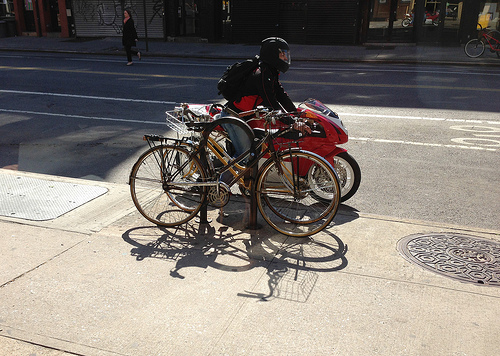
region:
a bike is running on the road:
[133, 26, 374, 237]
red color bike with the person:
[185, 41, 360, 199]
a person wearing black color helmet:
[254, 35, 294, 72]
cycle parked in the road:
[137, 125, 340, 234]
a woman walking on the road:
[116, 6, 147, 70]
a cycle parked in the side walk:
[463, 22, 498, 58]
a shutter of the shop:
[72, 0, 163, 50]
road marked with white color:
[383, 77, 478, 184]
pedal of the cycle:
[211, 165, 228, 205]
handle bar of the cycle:
[243, 102, 280, 131]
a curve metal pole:
[214, 117, 248, 134]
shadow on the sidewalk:
[136, 227, 305, 298]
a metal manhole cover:
[391, 224, 494, 289]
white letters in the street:
[451, 105, 497, 155]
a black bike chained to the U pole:
[157, 135, 282, 227]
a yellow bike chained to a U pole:
[194, 136, 319, 201]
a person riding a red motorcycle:
[174, 34, 341, 189]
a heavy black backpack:
[215, 57, 257, 99]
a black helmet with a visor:
[260, 35, 289, 63]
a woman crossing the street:
[117, 12, 144, 74]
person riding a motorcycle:
[176, 37, 363, 203]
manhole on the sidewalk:
[395, 231, 499, 288]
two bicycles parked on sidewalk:
[127, 106, 342, 238]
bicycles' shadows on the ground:
[120, 208, 351, 303]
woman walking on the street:
[117, 9, 145, 69]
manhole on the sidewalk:
[0, 168, 110, 223]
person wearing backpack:
[214, 35, 315, 194]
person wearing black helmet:
[216, 33, 309, 195]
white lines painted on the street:
[0, 89, 498, 152]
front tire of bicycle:
[462, 21, 498, 58]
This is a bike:
[126, 139, 463, 278]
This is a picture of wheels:
[118, 139, 423, 263]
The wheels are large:
[117, 154, 235, 204]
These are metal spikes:
[142, 115, 194, 252]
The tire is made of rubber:
[119, 184, 140, 201]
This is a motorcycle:
[294, 119, 332, 141]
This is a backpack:
[205, 54, 341, 142]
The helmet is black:
[255, 44, 307, 125]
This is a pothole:
[428, 232, 450, 247]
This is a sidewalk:
[41, 318, 91, 350]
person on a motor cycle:
[186, 28, 367, 227]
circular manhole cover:
[389, 231, 496, 286]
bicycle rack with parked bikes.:
[127, 92, 346, 244]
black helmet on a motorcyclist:
[252, 36, 301, 75]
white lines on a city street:
[379, 89, 429, 179]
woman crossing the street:
[114, 0, 147, 75]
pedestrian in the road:
[96, 0, 146, 71]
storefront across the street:
[368, 13, 448, 44]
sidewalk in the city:
[19, 191, 134, 343]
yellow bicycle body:
[207, 136, 239, 183]